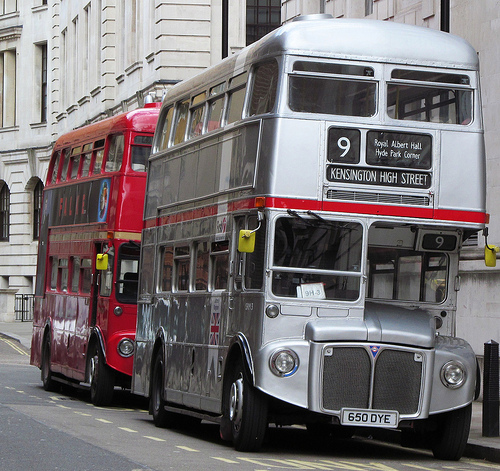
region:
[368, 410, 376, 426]
The letter is black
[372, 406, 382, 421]
The letter is black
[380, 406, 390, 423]
The letter is black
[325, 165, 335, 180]
The letter is white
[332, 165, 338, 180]
The letter is white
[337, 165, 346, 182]
The letter is white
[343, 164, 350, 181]
The letter is white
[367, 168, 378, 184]
The letter is white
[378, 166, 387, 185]
The letter is white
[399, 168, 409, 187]
The letter is white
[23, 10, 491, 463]
two buses are parked on the side of the street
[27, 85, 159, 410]
the bus in the back is red in color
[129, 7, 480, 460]
the bus up front is silver in color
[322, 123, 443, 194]
the information of the buses destination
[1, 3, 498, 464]
big building is to the right of the buses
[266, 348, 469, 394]
the silver buses headlights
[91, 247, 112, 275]
one of the red buses rear view mirrors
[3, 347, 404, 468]
a portion of the street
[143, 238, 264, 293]
a row of windows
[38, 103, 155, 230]
the bus has a second set of seats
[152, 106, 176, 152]
2nd floor window on silver bus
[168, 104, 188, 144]
2nd floor window on silver bus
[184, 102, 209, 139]
2nd floor window on silver bus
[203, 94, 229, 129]
2nd floor window on silver bus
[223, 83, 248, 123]
2nd floor window on silver bus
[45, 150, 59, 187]
2nd floor window on red bus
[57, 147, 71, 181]
2nd floor window on red bus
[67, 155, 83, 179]
2nd floor window on red bus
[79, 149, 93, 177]
2nd floor window on red bus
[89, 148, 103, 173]
2nd floor window on red bus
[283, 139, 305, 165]
the bus is silver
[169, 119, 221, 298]
the bus is 2 story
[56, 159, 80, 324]
the bus is a double decker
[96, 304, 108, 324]
the bus is red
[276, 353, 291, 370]
the light is off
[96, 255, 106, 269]
the mirror is yellow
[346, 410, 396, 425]
the tag is gray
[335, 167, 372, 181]
the word is white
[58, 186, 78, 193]
the banner is black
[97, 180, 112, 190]
the banner is blue